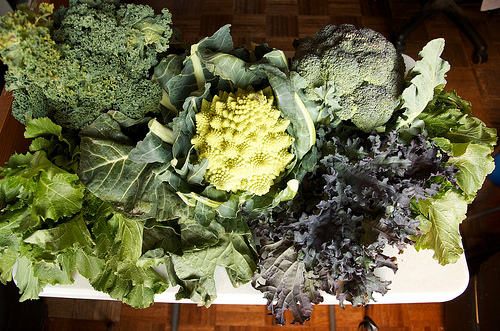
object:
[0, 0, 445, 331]
table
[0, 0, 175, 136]
broccoli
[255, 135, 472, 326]
vegetable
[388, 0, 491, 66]
legs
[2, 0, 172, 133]
kale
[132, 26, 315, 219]
cabbage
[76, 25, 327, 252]
leaves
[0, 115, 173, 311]
vegetables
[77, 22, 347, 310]
broccoli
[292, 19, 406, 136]
broccoli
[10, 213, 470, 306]
plate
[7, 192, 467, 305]
tray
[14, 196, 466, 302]
board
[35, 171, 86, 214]
line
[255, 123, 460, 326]
leaves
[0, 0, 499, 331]
floor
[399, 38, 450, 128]
leaf